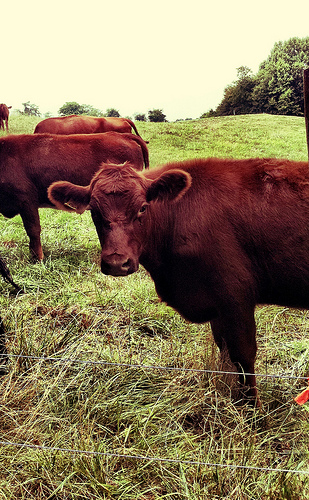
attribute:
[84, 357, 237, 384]
barbed wire — fence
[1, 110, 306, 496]
grass — tall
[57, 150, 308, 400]
cow — brown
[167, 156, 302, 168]
back fur — brown, thick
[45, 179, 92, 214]
ear — big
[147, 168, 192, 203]
ear — big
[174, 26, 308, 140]
trees — grove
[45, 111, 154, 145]
cow — distant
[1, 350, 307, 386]
wire — metal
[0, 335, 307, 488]
fence — metal, wire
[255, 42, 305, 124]
leaves — green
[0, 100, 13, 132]
cow — distant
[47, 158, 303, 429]
cow — brown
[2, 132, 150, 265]
cow — brown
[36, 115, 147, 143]
cow — brown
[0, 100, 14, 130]
cow — brown